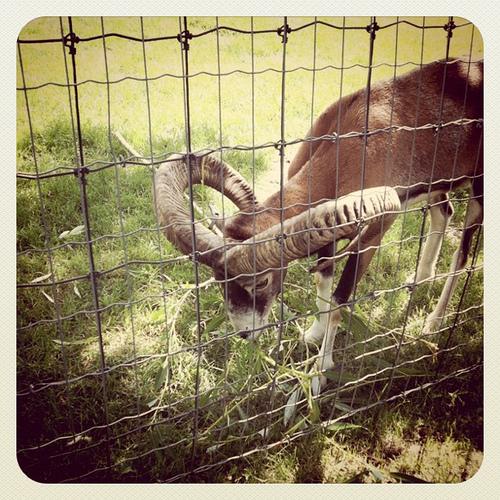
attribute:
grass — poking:
[295, 402, 352, 438]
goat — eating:
[150, 55, 482, 371]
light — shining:
[425, 47, 490, 99]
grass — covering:
[33, 339, 478, 471]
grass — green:
[19, 19, 491, 488]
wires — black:
[29, 24, 469, 471]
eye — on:
[250, 277, 268, 292]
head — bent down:
[152, 150, 395, 342]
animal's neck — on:
[221, 168, 358, 235]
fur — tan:
[363, 154, 400, 174]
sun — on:
[164, 53, 226, 86]